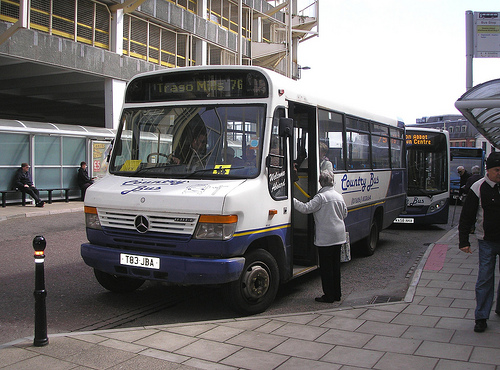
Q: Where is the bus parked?
A: At a bus stop.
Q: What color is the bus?
A: White.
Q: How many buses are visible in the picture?
A: Two.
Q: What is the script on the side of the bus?
A: Country Bus.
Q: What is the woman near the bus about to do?
A: Get on the bus.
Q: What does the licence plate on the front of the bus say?
A: T83 JBA.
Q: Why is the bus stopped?
A: To let on passengers.